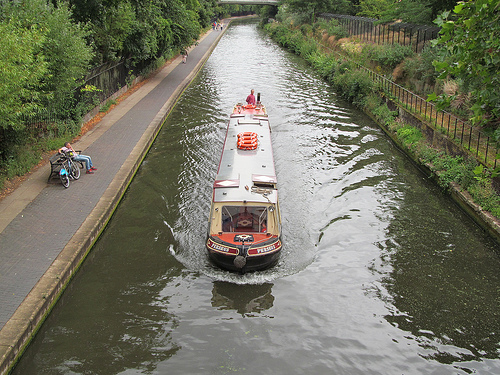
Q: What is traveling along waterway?
A: Boat.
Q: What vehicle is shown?
A: Boat.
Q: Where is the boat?
A: In the canal.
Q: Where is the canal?
A: Beside the road.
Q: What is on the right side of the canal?
A: A fence.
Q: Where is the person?
A: On the road.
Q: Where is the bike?
A: On the road.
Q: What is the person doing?
A: Sitting.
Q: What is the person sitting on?
A: A bench.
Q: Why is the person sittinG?
A: To rest.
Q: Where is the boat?
A: In the river.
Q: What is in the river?
A: A boat.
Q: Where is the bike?
A: Leaned against a bench.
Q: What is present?
A: A water voyage.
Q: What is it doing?
A: Sailing.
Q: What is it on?
A: Water.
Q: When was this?
A: Daytime.